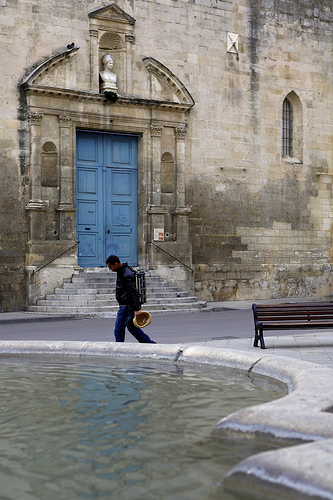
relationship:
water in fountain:
[17, 371, 144, 483] [1, 337, 327, 496]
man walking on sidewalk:
[106, 254, 157, 346] [8, 261, 74, 396]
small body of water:
[54, 382, 275, 500] [29, 335, 228, 490]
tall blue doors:
[81, 126, 133, 275] [70, 129, 134, 252]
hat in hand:
[126, 304, 156, 334] [129, 292, 145, 342]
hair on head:
[85, 253, 123, 285] [93, 255, 122, 301]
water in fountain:
[0, 350, 333, 500] [0, 344, 331, 500]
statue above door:
[100, 53, 118, 95] [78, 131, 142, 268]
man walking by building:
[104, 252, 154, 345] [7, 5, 315, 307]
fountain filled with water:
[1, 337, 327, 496] [7, 354, 283, 498]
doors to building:
[79, 133, 138, 272] [9, 11, 320, 287]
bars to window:
[283, 104, 289, 160] [279, 87, 305, 160]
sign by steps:
[152, 224, 165, 241] [39, 260, 220, 322]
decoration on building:
[99, 55, 114, 90] [7, 5, 315, 307]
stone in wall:
[231, 248, 244, 258] [188, 78, 319, 287]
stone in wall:
[238, 235, 255, 241] [147, 7, 320, 289]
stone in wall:
[274, 223, 288, 229] [147, 7, 320, 289]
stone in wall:
[277, 228, 291, 237] [147, 7, 320, 289]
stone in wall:
[306, 193, 322, 208] [147, 7, 320, 289]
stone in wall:
[279, 228, 295, 237] [160, 55, 321, 271]